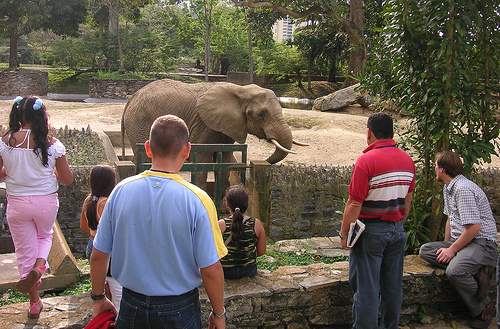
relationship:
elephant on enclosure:
[114, 73, 307, 184] [1, 62, 491, 207]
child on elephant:
[89, 114, 225, 329] [148, 71, 282, 136]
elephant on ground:
[121, 79, 311, 214] [0, 94, 498, 326]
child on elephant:
[214, 187, 276, 277] [122, 78, 297, 166]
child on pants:
[0, 95, 73, 318] [7, 188, 60, 280]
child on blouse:
[0, 95, 73, 318] [1, 133, 67, 195]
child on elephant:
[89, 114, 225, 329] [126, 64, 322, 167]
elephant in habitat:
[121, 79, 311, 214] [7, 60, 481, 237]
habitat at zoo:
[7, 60, 481, 237] [0, 55, 498, 327]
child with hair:
[217, 185, 265, 280] [230, 207, 250, 259]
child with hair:
[79, 165, 120, 277] [83, 175, 111, 231]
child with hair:
[0, 95, 73, 318] [13, 93, 46, 163]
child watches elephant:
[217, 185, 265, 280] [116, 74, 313, 168]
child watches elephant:
[79, 165, 120, 277] [116, 74, 313, 168]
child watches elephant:
[0, 95, 73, 318] [116, 74, 313, 168]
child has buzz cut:
[89, 114, 225, 329] [148, 110, 188, 162]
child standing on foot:
[0, 95, 73, 318] [14, 260, 43, 317]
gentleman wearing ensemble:
[420, 144, 499, 320] [420, 236, 499, 315]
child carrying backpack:
[89, 114, 225, 329] [76, 287, 125, 327]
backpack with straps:
[76, 287, 125, 327] [82, 306, 120, 326]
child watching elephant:
[0, 95, 73, 318] [112, 77, 294, 183]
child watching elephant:
[79, 165, 120, 277] [112, 77, 294, 183]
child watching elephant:
[89, 114, 225, 329] [112, 77, 294, 183]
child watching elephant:
[217, 185, 265, 280] [112, 77, 294, 183]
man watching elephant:
[338, 113, 416, 329] [112, 77, 294, 183]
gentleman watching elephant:
[419, 151, 499, 329] [112, 77, 294, 183]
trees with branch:
[0, 0, 499, 87] [186, 3, 213, 31]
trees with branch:
[0, 0, 499, 87] [322, 4, 370, 49]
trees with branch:
[0, 0, 499, 87] [13, 5, 73, 39]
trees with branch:
[0, 0, 499, 87] [385, 1, 455, 136]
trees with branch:
[0, 0, 499, 87] [118, 1, 146, 27]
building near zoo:
[271, 15, 306, 43] [2, 0, 498, 327]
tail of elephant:
[116, 88, 136, 159] [114, 73, 307, 184]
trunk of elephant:
[266, 123, 296, 163] [112, 77, 294, 183]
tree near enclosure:
[362, 4, 499, 254] [5, 67, 499, 270]